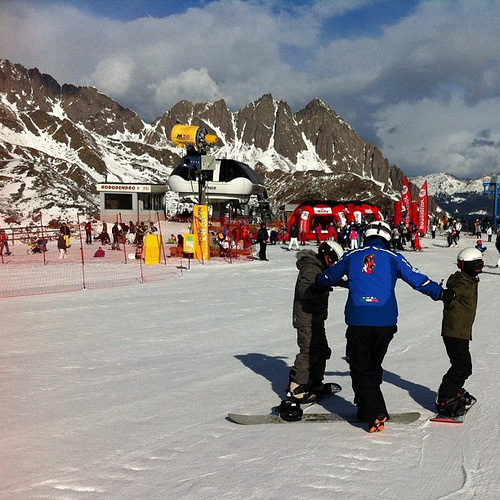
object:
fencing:
[1, 216, 259, 296]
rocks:
[149, 85, 441, 183]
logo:
[362, 252, 377, 274]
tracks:
[309, 439, 388, 497]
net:
[0, 228, 259, 299]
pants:
[345, 323, 395, 425]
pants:
[440, 333, 474, 398]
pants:
[289, 325, 334, 388]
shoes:
[369, 410, 389, 433]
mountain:
[0, 57, 465, 238]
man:
[284, 240, 350, 401]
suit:
[287, 246, 342, 385]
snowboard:
[427, 394, 479, 426]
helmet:
[363, 221, 392, 242]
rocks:
[193, 99, 407, 180]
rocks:
[8, 62, 160, 142]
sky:
[72, 1, 494, 138]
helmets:
[456, 246, 484, 263]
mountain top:
[294, 90, 345, 130]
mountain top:
[240, 87, 295, 130]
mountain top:
[172, 95, 232, 121]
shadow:
[233, 350, 293, 398]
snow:
[1, 300, 218, 497]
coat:
[320, 238, 444, 330]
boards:
[227, 411, 423, 426]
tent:
[276, 196, 391, 247]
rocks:
[28, 87, 342, 158]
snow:
[234, 139, 287, 171]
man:
[324, 220, 444, 435]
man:
[433, 245, 485, 419]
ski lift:
[164, 150, 266, 215]